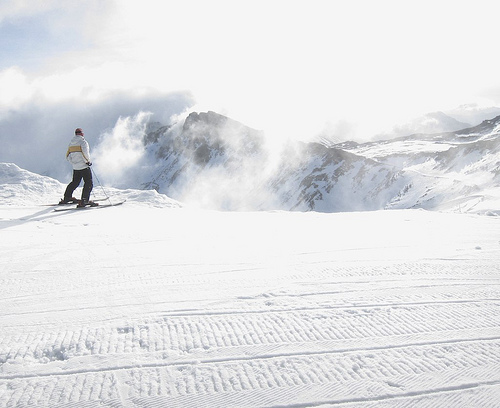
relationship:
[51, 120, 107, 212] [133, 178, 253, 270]
man on cliff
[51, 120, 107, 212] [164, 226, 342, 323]
man in snow